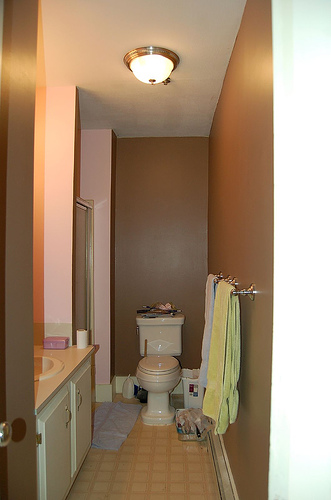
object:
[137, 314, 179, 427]
toilet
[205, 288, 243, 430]
towel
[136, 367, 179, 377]
seat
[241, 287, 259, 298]
towel rack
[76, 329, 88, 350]
roll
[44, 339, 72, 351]
container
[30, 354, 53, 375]
sink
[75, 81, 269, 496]
bathroom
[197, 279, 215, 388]
towel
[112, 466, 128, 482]
pattern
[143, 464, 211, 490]
floor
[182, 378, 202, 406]
trashcan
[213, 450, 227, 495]
trim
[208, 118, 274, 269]
wall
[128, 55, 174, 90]
light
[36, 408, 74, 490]
cabinet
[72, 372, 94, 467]
cabinet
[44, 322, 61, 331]
trim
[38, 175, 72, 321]
wall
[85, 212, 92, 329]
shower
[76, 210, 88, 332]
door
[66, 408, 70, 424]
handle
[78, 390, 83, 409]
handle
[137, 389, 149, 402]
plunger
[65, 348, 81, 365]
counter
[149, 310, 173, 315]
curling iron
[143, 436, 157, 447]
tile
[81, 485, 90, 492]
tile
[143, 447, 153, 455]
tile